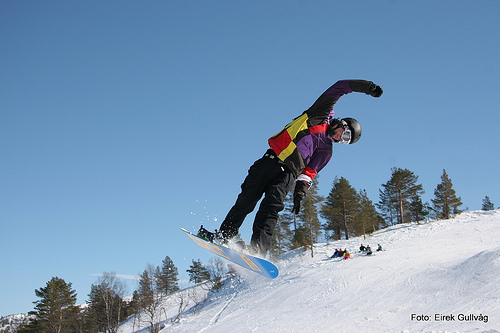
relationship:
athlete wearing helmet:
[213, 80, 383, 260] [342, 117, 362, 143]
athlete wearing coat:
[213, 80, 383, 260] [223, 78, 379, 250]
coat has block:
[223, 78, 379, 250] [269, 133, 297, 157]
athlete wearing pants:
[213, 80, 383, 260] [197, 142, 293, 259]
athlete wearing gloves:
[213, 80, 383, 260] [347, 61, 381, 117]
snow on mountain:
[96, 207, 498, 331] [90, 193, 496, 331]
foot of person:
[198, 220, 235, 260] [217, 70, 383, 255]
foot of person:
[243, 238, 267, 260] [198, 74, 383, 279]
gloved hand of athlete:
[362, 78, 385, 101] [213, 80, 383, 260]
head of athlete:
[326, 110, 363, 144] [213, 80, 383, 260]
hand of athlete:
[292, 193, 304, 211] [203, 77, 381, 257]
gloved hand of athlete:
[369, 83, 383, 98] [203, 77, 381, 257]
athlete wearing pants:
[213, 80, 383, 260] [220, 142, 300, 258]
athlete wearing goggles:
[213, 80, 383, 260] [340, 119, 352, 144]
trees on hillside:
[326, 166, 493, 229] [0, 201, 498, 331]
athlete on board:
[213, 80, 383, 260] [176, 224, 280, 279]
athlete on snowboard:
[213, 80, 383, 260] [178, 222, 283, 278]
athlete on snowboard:
[213, 80, 383, 260] [177, 224, 278, 281]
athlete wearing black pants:
[213, 80, 383, 260] [219, 149, 297, 256]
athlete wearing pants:
[213, 80, 383, 260] [216, 160, 295, 271]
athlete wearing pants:
[213, 80, 383, 260] [204, 159, 439, 297]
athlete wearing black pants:
[213, 80, 383, 260] [223, 152, 293, 246]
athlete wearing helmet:
[213, 80, 383, 260] [343, 109, 366, 149]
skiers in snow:
[326, 235, 388, 265] [316, 275, 413, 303]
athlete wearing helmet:
[213, 80, 383, 260] [346, 115, 361, 144]